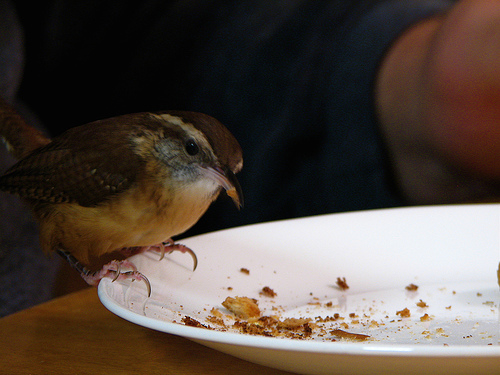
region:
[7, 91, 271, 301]
This is a bird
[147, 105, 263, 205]
Head of a bird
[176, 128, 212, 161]
Eye of a bird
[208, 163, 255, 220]
Peak of a bird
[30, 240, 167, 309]
Leg of a bird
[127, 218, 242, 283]
Leg of a bird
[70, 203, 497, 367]
This is a white plate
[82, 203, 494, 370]
This is a plate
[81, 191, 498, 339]
a plate with food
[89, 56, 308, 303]
a bird on a plate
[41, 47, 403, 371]
a bird on a white plate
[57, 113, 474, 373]
a plate with a bird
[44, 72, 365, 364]
a white plate with a bird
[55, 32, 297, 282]
a small bird on a plate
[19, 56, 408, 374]
a small bird on a white plate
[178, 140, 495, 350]
a plate with crumbs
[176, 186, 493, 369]
a plate on a table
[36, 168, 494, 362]
a white plate on a table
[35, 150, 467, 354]
a table with a plate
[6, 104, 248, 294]
a brid on a plate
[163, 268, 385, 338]
bread crumbs on a plate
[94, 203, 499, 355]
a round white plate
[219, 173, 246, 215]
a black beck on a bird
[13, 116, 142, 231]
brown feathers on a bird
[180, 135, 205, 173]
a eye on a bird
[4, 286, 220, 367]
a brown table top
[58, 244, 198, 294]
gray feet on a bird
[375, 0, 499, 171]
a neck of a person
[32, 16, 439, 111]
a drak blue shirt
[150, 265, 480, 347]
THE CRUMBS ARE ON THE PLATE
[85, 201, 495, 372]
THE PLATE IS WHITE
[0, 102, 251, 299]
THE BIRD IS NOT AFRAID OF PEOPLE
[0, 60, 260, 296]
THE BIRD IS EATING CRUMBS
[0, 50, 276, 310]
THE BIRD IS ON THE EDGE OF THE PLATE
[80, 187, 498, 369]
THE PLATE IS ON THE TABLE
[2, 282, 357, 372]
THE TABLE IS BROWN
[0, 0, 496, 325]
THIS IS A PERSON SITTING AT THE TABLE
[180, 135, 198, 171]
THIS IS THE LITTLE BIRD'S EYE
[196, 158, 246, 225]
THIS IS THE LITTLE BIRDS FEET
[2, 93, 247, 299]
Bird on the plate.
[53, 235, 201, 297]
Black and tan feet on the bird.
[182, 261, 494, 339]
Crumbs on the plate.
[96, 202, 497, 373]
White plate on the table.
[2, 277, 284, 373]
Brown wood on the surface.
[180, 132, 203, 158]
Black eye on the bird.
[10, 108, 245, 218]
Grey feathers on top of the bird.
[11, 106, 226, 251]
Yellow underside of the bird.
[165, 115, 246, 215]
Gray and brown beak on bird.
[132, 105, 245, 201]
White feathers on the head of the bird.